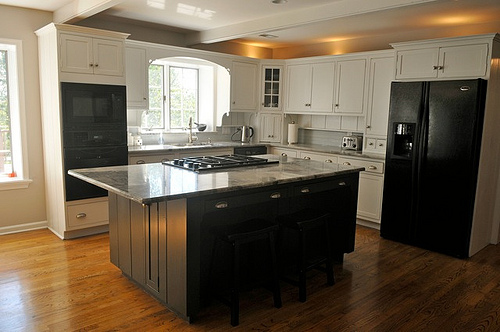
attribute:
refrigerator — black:
[381, 81, 483, 258]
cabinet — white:
[58, 29, 127, 80]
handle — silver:
[77, 214, 87, 218]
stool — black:
[211, 219, 282, 328]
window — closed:
[166, 64, 201, 132]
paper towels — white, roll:
[286, 122, 300, 144]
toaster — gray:
[340, 135, 363, 152]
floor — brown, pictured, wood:
[2, 224, 500, 330]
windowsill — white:
[1, 176, 33, 188]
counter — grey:
[273, 139, 383, 164]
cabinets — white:
[287, 62, 369, 115]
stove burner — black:
[166, 153, 279, 169]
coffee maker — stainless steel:
[232, 124, 254, 143]